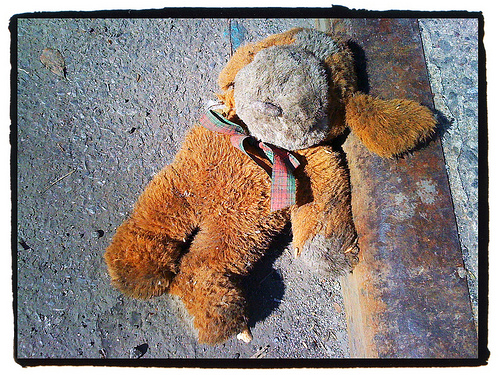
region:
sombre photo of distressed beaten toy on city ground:
[55, 20, 456, 357]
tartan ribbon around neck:
[181, 90, 306, 215]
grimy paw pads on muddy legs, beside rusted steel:
[291, 145, 371, 370]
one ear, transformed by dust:
[340, 80, 445, 165]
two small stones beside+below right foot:
[85, 210, 146, 360]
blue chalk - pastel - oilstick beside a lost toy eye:
[215, 15, 250, 50]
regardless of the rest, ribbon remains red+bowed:
[193, 103, 306, 218]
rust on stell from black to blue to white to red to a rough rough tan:
[340, 127, 481, 372]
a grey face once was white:
[222, 27, 352, 149]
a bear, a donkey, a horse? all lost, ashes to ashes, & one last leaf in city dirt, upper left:
[30, 18, 477, 357]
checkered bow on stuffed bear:
[210, 108, 295, 213]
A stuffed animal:
[184, 46, 343, 290]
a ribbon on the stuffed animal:
[206, 111, 293, 188]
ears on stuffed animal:
[348, 94, 437, 152]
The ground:
[48, 58, 158, 133]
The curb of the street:
[341, 216, 461, 297]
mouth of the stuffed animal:
[252, 97, 297, 121]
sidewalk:
[444, 69, 486, 113]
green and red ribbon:
[261, 171, 311, 208]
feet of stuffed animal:
[186, 273, 263, 335]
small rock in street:
[120, 341, 150, 363]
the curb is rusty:
[329, 150, 469, 322]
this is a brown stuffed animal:
[72, 22, 414, 349]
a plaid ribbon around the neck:
[181, 102, 314, 211]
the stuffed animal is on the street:
[117, 31, 403, 312]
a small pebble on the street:
[112, 336, 150, 359]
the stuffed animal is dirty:
[197, 23, 410, 284]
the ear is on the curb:
[333, 75, 440, 176]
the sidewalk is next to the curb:
[422, 28, 479, 191]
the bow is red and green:
[185, 97, 315, 209]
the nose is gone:
[263, 35, 309, 89]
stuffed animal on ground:
[75, 26, 432, 351]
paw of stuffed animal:
[170, 270, 251, 355]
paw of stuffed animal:
[108, 232, 178, 312]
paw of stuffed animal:
[303, 223, 360, 318]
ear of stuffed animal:
[354, 97, 436, 167]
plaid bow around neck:
[201, 125, 303, 212]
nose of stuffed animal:
[273, 56, 295, 84]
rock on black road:
[86, 226, 106, 243]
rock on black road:
[127, 340, 164, 356]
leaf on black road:
[40, 49, 79, 91]